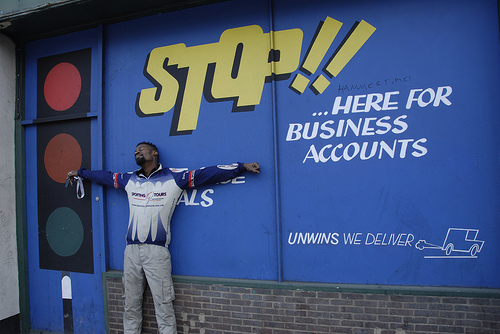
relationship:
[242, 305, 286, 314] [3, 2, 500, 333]
brick in wall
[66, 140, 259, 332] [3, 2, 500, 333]
man against wall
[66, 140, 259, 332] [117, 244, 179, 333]
man wearing pants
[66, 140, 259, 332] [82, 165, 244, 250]
man wearing shirt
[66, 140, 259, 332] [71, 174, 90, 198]
man holding key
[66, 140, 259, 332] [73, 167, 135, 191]
man with arm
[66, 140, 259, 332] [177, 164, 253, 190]
man with arm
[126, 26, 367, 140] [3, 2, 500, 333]
word on wall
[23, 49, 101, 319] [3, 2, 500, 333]
stoplight on wall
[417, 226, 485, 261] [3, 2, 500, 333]
truck on wall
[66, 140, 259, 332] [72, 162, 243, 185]
man outstretches arms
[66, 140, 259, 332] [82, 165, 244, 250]
man wearing jacket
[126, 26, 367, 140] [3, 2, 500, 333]
sign on wall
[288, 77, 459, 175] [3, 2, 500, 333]
sign on wall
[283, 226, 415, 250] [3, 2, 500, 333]
sign on wall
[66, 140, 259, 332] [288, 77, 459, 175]
man near sign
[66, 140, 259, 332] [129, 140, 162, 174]
man has head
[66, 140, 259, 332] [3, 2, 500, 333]
man against building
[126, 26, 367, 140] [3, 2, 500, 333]
word on building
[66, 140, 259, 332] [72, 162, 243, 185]
man with arms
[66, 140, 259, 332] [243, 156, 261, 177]
man has hand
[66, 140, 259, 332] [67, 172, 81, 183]
man has hand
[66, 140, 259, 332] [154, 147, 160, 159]
man has ear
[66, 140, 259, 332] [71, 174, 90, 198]
man holding keys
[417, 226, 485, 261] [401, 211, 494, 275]
drawing of a truck